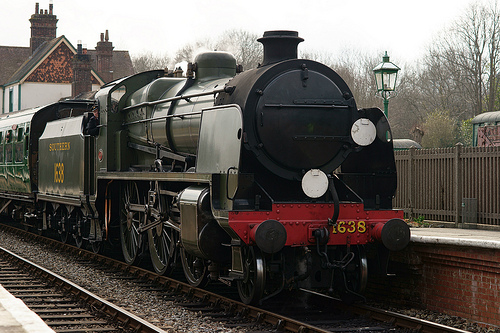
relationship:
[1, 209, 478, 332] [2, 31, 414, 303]
tracks are in front of train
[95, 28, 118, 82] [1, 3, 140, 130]
chimney on top of building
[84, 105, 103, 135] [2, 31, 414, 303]
person on train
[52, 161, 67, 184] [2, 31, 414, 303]
numbers are on train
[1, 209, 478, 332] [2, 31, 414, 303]
tracks are beside train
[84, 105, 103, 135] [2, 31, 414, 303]
person hanging out of train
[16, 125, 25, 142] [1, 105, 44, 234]
window on car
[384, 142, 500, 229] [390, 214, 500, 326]
fence behind platform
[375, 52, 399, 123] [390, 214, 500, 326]
lamppost on platform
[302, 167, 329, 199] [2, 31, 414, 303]
light on front of train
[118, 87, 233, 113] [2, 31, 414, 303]
pope on train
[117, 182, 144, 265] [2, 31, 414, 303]
wheel under train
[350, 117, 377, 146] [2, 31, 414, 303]
circle on front of train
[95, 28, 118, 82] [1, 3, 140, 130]
chimney on building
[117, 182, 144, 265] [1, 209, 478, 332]
wheel on tracks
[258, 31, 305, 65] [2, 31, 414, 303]
smoke stack on top of train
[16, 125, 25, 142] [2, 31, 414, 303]
window on train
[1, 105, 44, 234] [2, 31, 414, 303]
car on train